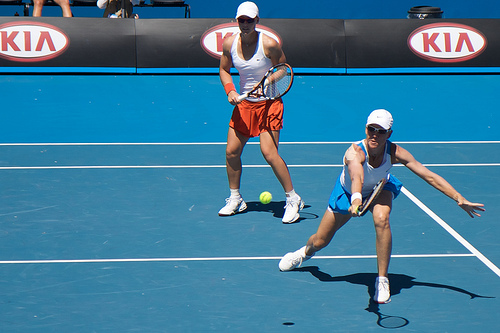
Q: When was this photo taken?
A: Day time.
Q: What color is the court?
A: Blue.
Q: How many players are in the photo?
A: Two.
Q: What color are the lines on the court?
A: White.